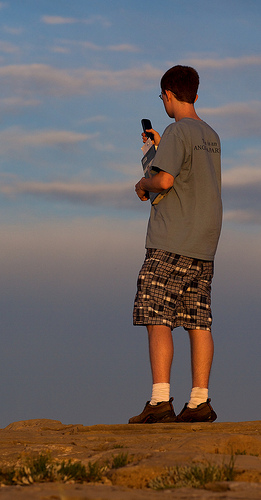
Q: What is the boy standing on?
A: Stone.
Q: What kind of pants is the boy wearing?
A: Shorts.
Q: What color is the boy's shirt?
A: Gray.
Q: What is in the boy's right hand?
A: Cell phone.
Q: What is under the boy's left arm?
A: A book.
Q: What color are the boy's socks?
A: White.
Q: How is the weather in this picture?
A: Cloudy.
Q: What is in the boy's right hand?
A: A phone.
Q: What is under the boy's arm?
A: A book.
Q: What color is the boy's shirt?
A: Grey.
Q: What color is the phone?
A: Black.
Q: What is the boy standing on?
A: Rocks.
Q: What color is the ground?
A: Brown.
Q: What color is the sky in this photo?
A: Blue.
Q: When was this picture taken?
A: Sunset.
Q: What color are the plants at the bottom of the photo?
A: Green.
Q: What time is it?
A: Evening.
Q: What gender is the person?
A: Male.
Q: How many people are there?
A: One.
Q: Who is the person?
A: A man.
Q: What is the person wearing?
A: Shorts.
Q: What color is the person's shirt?
A: Gray.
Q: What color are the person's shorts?
A: Black and brown.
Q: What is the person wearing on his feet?
A: Socks and shoes.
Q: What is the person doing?
A: Looking at phone.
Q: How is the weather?
A: Cloudy.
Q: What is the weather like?
A: Warm.